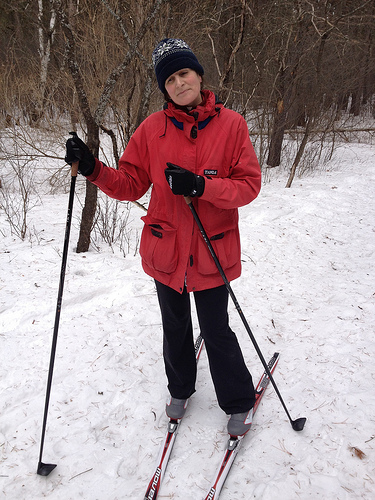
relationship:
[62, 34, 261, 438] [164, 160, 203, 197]
skier wearing glove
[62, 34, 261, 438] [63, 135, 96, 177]
skier wearing glove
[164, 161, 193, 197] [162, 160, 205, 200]
hand wearing glove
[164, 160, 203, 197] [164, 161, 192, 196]
glove on hand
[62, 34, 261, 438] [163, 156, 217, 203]
skier wearing glove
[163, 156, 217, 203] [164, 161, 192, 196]
glove on hand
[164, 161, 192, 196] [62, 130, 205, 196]
hand wearing glove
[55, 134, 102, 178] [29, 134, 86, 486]
gloved hand holding ski pole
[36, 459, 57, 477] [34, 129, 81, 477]
disc support on pole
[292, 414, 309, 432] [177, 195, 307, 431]
disc support on pole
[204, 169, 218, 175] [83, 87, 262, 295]
logo on coat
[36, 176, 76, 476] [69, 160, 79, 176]
pole with handle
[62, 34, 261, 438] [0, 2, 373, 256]
skier skiing in woods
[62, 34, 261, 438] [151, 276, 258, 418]
skier wearing pants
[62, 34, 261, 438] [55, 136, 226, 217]
skier wearing gloves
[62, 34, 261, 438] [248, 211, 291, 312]
skier standing on snow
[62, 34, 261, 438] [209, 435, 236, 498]
skier standing on skis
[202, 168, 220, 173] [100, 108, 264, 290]
logo on coat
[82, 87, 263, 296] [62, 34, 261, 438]
coat on skier